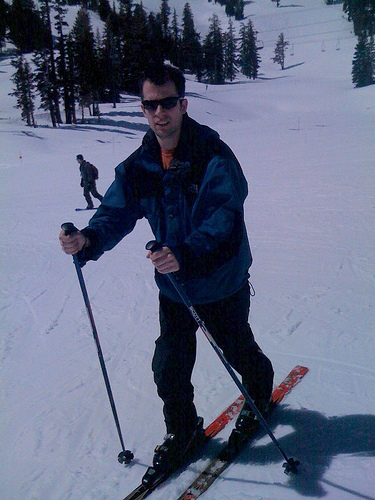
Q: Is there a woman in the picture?
A: No, there are no women.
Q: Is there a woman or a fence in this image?
A: No, there are no women or fences.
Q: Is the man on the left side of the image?
A: Yes, the man is on the left of the image.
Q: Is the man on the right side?
A: No, the man is on the left of the image.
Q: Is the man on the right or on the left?
A: The man is on the left of the image.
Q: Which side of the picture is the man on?
A: The man is on the left of the image.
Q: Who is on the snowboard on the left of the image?
A: The man is on the snow board.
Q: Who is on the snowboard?
A: The man is on the snow board.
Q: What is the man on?
A: The man is on the snow board.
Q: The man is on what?
A: The man is on the snow board.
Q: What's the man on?
A: The man is on the snow board.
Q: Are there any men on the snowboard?
A: Yes, there is a man on the snowboard.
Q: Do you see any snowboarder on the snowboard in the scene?
A: No, there is a man on the snowboard.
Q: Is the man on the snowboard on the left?
A: Yes, the man is on the snowboard.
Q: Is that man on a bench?
A: No, the man is on the snowboard.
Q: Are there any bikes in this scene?
A: No, there are no bikes.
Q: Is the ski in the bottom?
A: Yes, the ski is in the bottom of the image.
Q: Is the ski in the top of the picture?
A: No, the ski is in the bottom of the image.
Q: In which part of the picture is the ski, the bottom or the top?
A: The ski is in the bottom of the image.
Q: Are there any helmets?
A: No, there are no helmets.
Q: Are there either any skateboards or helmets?
A: No, there are no helmets or skateboards.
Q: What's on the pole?
A: The shoe is on the pole.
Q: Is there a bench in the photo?
A: No, there are no benches.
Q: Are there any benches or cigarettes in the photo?
A: No, there are no benches or cigarettes.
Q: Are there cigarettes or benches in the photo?
A: No, there are no benches or cigarettes.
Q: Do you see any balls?
A: No, there are no balls.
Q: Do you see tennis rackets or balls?
A: No, there are no balls or tennis rackets.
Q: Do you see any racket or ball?
A: No, there are no balls or rackets.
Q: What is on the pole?
A: The shoe is on the pole.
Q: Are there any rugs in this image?
A: No, there are no rugs.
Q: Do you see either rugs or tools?
A: No, there are no rugs or tools.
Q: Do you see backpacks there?
A: Yes, there is a backpack.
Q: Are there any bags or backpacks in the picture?
A: Yes, there is a backpack.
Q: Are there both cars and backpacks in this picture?
A: No, there is a backpack but no cars.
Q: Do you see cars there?
A: No, there are no cars.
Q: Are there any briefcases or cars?
A: No, there are no cars or briefcases.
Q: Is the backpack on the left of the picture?
A: Yes, the backpack is on the left of the image.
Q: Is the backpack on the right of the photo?
A: No, the backpack is on the left of the image.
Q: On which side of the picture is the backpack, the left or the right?
A: The backpack is on the left of the image.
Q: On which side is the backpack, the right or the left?
A: The backpack is on the left of the image.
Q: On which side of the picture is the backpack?
A: The backpack is on the left of the image.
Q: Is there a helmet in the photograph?
A: No, there are no helmets.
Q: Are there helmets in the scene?
A: No, there are no helmets.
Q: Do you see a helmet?
A: No, there are no helmets.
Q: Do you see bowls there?
A: No, there are no bowls.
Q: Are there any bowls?
A: No, there are no bowls.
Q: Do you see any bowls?
A: No, there are no bowls.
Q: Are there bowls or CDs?
A: No, there are no bowls or cds.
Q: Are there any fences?
A: No, there are no fences.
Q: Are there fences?
A: No, there are no fences.